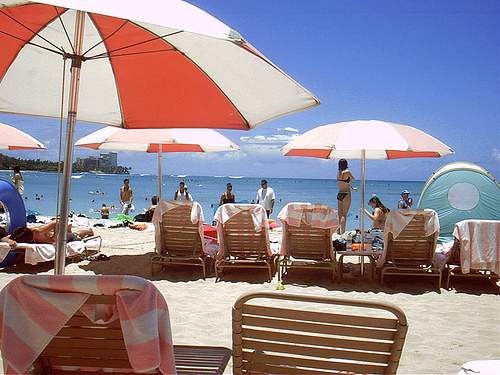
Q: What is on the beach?
A: People.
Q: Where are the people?
A: On the beach.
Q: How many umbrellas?
A: 4.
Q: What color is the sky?
A: Blue.